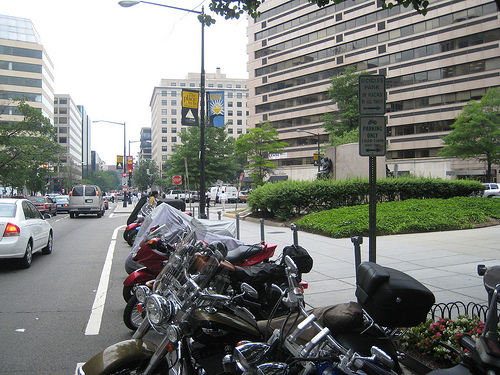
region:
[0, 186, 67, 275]
white car on the street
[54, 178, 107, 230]
car driving on the street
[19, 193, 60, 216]
car driving on the street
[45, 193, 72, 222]
car driving on the street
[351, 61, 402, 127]
sign with green writing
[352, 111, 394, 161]
sign with green writing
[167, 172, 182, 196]
stop sign on a pole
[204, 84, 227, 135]
blue banner with design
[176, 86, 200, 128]
black banner with design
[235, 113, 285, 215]
tree with green leaves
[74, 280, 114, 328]
white line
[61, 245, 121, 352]
white line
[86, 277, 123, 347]
white line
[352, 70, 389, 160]
signs showing parking locations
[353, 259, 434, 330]
storage box on back of motorcycle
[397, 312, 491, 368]
flowers in planter along street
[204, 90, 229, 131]
blue sign hanging from light pole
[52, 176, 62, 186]
traffic light on red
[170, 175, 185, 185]
stop sign in the distance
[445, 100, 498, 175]
tree growing near building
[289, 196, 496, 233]
small hill covered in greenery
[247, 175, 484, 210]
small row of bushes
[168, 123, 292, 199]
trees growing in a city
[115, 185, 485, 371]
A line of parked motorcycles.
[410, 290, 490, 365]
Flowers.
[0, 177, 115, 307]
Traffic.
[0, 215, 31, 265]
The car's brake lights are on.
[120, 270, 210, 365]
The motorcycle's headlights.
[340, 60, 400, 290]
A street sign.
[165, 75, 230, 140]
Two banners attached to a streetlight.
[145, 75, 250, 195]
A high-rise building with many windows.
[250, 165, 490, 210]
A large hedge.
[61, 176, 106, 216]
A gray van on the street.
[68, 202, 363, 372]
lots of motorcycles parked by the street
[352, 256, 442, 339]
motorcycle black storage container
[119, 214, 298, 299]
red motorcycle parked in the street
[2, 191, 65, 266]
white car driving in the street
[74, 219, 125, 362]
long white painted line on the street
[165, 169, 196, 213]
red and white Stop sign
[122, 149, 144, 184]
street light with red light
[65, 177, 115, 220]
large gray van driving in the street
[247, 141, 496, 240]
lots of green bushes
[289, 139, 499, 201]
car parking brick garage